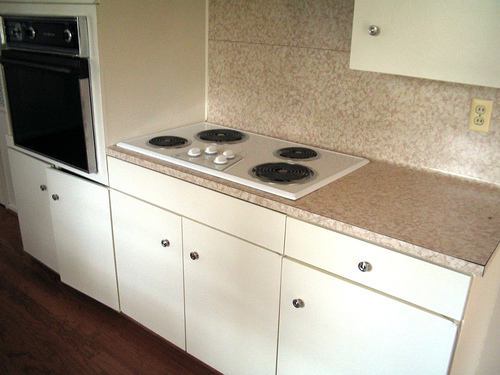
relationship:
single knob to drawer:
[363, 20, 382, 43] [272, 213, 474, 315]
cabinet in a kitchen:
[347, 0, 499, 89] [2, 2, 483, 372]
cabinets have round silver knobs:
[3, 150, 456, 372] [157, 234, 209, 268]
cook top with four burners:
[118, 107, 368, 203] [146, 122, 329, 199]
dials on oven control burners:
[213, 155, 228, 164] [178, 135, 243, 174]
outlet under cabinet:
[462, 88, 482, 133] [344, 2, 479, 109]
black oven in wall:
[1, 15, 91, 173] [0, 0, 213, 190]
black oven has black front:
[1, 15, 91, 173] [0, 14, 112, 171]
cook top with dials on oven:
[118, 120, 368, 202] [213, 155, 228, 164]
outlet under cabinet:
[469, 98, 492, 132] [340, 0, 484, 117]